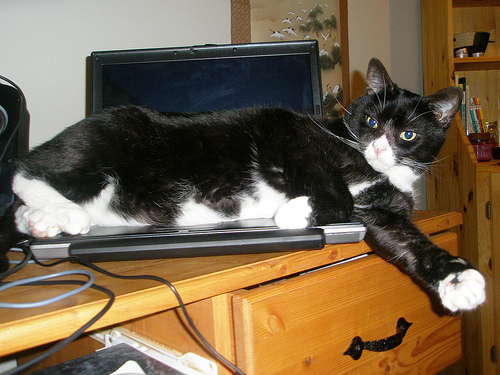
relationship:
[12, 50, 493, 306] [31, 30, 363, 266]
cat lying on laptop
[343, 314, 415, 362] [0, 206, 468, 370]
handle on desk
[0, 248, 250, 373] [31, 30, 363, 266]
cord coming from laptop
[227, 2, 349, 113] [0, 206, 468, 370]
decoration behind desk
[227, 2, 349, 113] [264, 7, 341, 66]
decoration has birds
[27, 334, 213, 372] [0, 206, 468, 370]
keyboard on desk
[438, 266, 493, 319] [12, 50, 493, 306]
paw on cat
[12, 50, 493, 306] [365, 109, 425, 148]
cat has eyes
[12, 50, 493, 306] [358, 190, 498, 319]
cat has arm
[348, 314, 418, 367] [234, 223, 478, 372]
handle in drawer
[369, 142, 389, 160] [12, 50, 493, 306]
nose tip in cat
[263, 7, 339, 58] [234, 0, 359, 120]
birds are in picture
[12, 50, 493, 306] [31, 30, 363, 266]
cat laying across laptop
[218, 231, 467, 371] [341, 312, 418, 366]
drawer with handle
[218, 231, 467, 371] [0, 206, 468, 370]
drawer on desk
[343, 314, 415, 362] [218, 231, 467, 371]
handle on drawer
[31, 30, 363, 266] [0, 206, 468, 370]
laptop on top of desk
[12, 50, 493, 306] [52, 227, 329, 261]
cat lying across keyboard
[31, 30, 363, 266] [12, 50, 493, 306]
laptop has cat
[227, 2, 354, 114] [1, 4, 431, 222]
decoration on wall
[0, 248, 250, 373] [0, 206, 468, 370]
cord on top of desk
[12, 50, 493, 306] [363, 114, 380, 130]
cat with cat eye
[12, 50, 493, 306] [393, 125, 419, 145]
cat with eye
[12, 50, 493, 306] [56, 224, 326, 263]
cat resting on keyboard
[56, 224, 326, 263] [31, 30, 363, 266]
keyboard of laptop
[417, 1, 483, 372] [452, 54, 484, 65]
cabinet with shelf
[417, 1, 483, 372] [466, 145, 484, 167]
cabinet with shelf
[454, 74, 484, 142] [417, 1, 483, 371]
books in shelf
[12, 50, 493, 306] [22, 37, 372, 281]
cat lying on laptop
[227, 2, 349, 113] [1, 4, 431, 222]
decoration on wall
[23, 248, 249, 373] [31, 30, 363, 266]
cord of laptop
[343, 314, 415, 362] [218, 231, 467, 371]
handle of drawer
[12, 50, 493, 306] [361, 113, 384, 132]
cat with eye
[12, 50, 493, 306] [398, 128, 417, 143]
cat with cat eye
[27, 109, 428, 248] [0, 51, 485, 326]
fur on cat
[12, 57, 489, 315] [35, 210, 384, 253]
cat on keyboard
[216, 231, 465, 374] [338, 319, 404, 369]
drawer with handle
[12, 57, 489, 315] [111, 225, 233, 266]
cat on laptop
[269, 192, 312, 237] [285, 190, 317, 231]
paw on laptop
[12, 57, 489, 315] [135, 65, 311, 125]
cat on laptop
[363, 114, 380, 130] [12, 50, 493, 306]
cat eye of a cat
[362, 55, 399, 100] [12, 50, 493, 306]
ear of a cat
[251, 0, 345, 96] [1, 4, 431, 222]
birds on wall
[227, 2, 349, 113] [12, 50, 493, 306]
decoration behind cat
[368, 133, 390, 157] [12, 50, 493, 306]
nose of a cat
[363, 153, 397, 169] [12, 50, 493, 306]
mouth of a cat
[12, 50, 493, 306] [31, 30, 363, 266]
cat on laptop